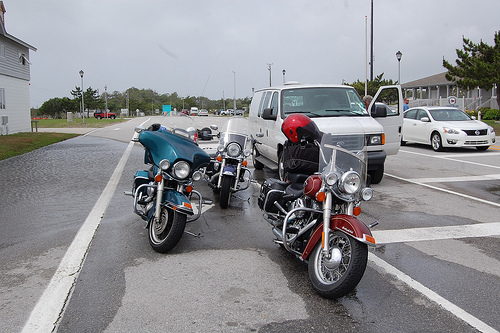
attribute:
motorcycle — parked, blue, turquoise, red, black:
[120, 124, 215, 257]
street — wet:
[4, 114, 498, 329]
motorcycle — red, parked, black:
[259, 135, 376, 301]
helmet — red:
[280, 113, 324, 146]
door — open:
[368, 84, 407, 160]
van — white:
[246, 82, 405, 188]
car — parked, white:
[397, 104, 498, 153]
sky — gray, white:
[0, 1, 495, 108]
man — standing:
[358, 94, 386, 115]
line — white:
[17, 109, 158, 332]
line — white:
[362, 250, 494, 333]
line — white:
[383, 172, 499, 210]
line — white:
[398, 146, 498, 170]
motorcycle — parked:
[208, 112, 260, 212]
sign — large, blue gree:
[160, 103, 176, 114]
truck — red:
[93, 107, 119, 124]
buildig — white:
[1, 2, 41, 137]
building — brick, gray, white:
[2, 2, 41, 137]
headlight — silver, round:
[339, 171, 360, 199]